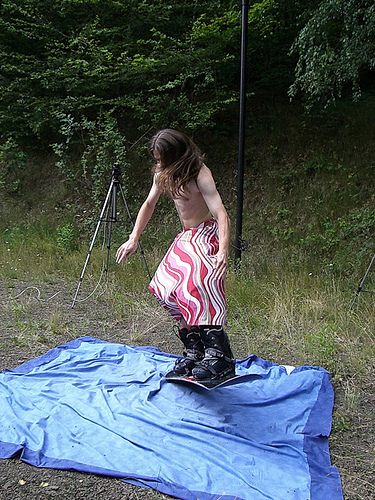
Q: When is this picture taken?
A: Daytime.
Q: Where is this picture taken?
A: Outside in woods.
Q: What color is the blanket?
A: Blue.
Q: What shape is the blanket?
A: Square.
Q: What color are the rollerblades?
A: Black.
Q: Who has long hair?
A: The rollerblader.